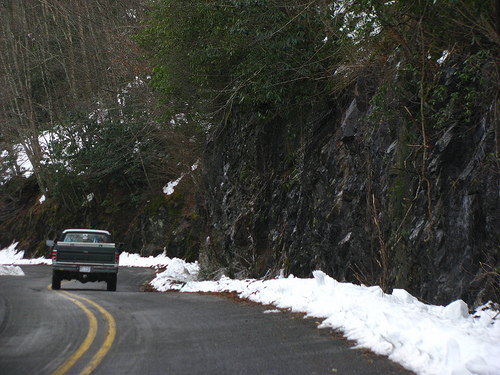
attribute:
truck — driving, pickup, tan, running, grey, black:
[50, 224, 122, 290]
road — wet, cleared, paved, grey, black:
[2, 256, 415, 374]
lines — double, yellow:
[47, 276, 115, 374]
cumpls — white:
[166, 264, 499, 374]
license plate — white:
[77, 268, 94, 277]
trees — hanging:
[1, 5, 146, 163]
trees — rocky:
[132, 10, 496, 287]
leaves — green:
[147, 2, 495, 261]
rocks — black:
[195, 59, 499, 303]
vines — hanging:
[374, 107, 422, 280]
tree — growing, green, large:
[149, 2, 340, 257]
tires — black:
[49, 275, 120, 294]